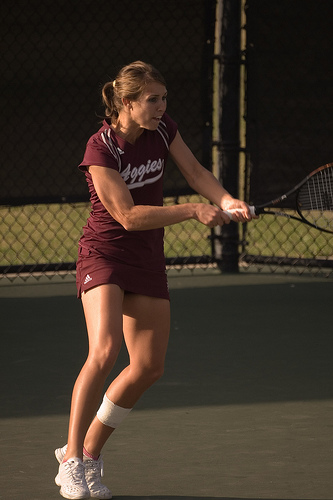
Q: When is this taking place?
A: Daytime.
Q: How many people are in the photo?
A: One.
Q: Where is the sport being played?
A: Tennis court.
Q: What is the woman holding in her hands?
A: Tennis racket.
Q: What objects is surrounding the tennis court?
A: Fence.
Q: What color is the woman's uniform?
A: Maroon and white.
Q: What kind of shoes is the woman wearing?
A: Sneakers.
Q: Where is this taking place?
A: At a tennis court.